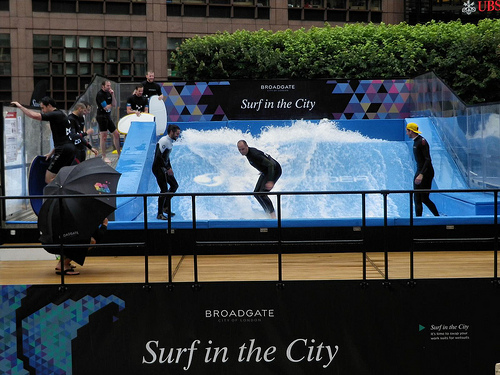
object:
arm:
[414, 138, 431, 185]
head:
[102, 80, 111, 91]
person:
[95, 80, 122, 163]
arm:
[161, 147, 175, 176]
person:
[151, 124, 180, 220]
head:
[406, 122, 422, 137]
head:
[237, 139, 249, 155]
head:
[168, 124, 181, 141]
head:
[144, 70, 155, 83]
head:
[39, 96, 57, 113]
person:
[11, 97, 79, 184]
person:
[126, 84, 149, 117]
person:
[237, 139, 283, 220]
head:
[135, 85, 144, 96]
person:
[405, 122, 440, 217]